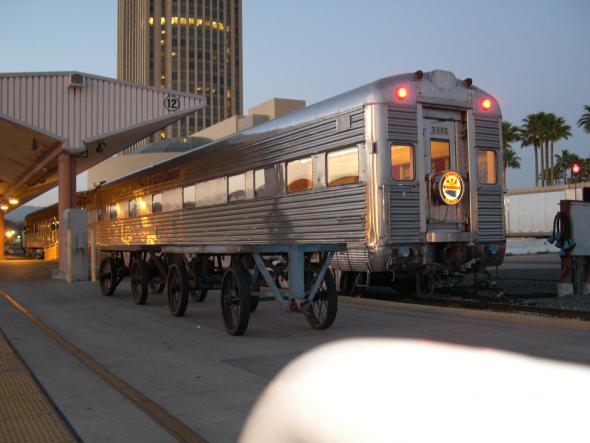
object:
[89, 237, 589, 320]
tracks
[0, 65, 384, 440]
station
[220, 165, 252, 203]
window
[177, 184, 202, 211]
window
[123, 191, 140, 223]
window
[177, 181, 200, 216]
window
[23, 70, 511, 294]
train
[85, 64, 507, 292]
train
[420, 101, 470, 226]
door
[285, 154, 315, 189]
window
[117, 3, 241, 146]
building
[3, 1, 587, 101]
sky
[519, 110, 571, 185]
palm tree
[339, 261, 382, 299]
wheels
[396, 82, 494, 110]
lights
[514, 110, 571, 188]
palm trees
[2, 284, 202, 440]
line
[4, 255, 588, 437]
ground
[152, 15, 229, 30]
lights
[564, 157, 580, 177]
light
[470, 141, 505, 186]
window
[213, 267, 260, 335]
wheels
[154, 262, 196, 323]
wheels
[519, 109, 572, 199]
palm tree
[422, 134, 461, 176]
window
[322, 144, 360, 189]
window